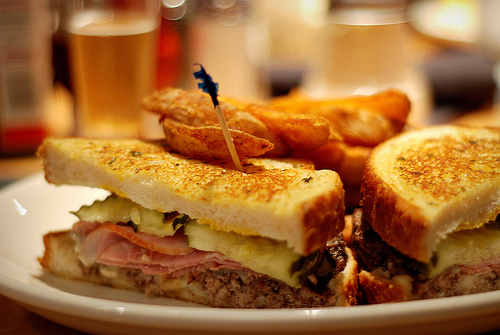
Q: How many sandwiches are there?
A: One, cut in half.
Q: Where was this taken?
A: At a restaurant.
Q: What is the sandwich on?
A: A plate.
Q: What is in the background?
A: Drinks and condiments.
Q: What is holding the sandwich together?
A: A toothpick.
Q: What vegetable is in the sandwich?
A: A pickle.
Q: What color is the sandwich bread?
A: Golden brown.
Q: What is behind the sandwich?
A: French fries.